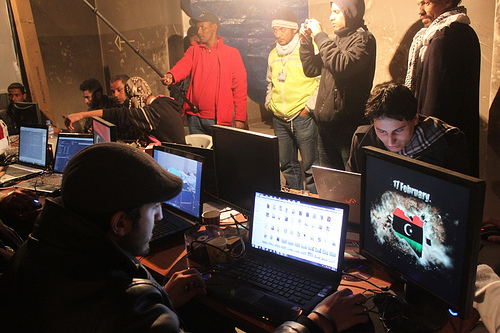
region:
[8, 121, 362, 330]
a row of four laptops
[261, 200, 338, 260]
several small icons on the screen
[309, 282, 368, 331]
hand on the mouse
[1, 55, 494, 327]
people sitting around a table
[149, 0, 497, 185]
people standing behind the table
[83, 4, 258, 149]
man holding a microphone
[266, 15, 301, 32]
white band around the head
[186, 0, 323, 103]
blue artwork on the wall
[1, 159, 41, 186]
silver keyboard on the laptop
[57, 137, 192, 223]
dark hat on the head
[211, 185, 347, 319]
the laptop on the table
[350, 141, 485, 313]
the black moniter on the table top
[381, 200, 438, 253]
the flag on the screen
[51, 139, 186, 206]
the hat on the mans head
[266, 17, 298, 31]
the band on the mans head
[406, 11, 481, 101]
the scarf on the mans neck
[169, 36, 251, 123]
the red sweater on the man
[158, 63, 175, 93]
the hand on the boom mic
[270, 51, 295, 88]
the chain on the mans shirt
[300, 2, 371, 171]
the man holding the camera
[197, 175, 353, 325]
black open laptop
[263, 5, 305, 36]
black and grey hat on person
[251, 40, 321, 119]
yellow long sleeve sweater on man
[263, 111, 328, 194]
pair of blue jeans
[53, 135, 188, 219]
black paper boy hat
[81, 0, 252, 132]
man holding boom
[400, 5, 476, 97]
white scarf around person's neck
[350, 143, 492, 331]
stand alone black monitor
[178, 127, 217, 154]
white plastic chair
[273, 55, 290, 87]
hanging badge around neck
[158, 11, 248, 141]
person wearing a red jacket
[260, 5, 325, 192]
person wearing yellow shirt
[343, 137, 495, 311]
computer monitor on the table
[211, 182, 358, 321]
laptop on the table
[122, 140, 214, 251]
laptop on the table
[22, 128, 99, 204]
laptop on the table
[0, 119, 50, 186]
laptop on the table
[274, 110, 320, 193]
pair of blue jeans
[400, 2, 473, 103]
white scarf around a neck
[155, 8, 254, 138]
person wearing a blue hat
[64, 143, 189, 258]
head of a person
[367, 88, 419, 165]
head of a person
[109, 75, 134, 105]
head of a person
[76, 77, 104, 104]
head of a person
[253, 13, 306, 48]
head of a person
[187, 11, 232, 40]
head of a person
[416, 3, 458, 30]
head of a person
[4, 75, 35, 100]
head of a person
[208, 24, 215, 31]
ear of a person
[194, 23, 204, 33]
nose of a person